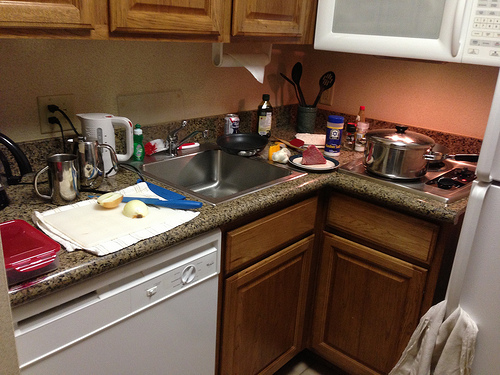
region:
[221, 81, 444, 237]
a kitchen counter top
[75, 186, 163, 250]
a sliced onion on a paper towel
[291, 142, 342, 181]
a piece of red meat on a saucer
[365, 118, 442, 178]
a silver pot on the stove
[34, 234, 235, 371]
dish washer under counter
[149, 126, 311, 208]
stain steel sink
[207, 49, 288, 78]
paper towel holder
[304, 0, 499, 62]
a white marcowave under cabinet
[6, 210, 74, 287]
a bowl with a red top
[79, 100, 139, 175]
a white water pitcher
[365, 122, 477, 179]
a pot on a stove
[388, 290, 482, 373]
a towel hanging on the handle of a refrigerator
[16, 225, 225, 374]
a white dishwasher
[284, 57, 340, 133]
three black utensils in a crock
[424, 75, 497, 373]
a white refrigerator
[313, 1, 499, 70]
a white microwave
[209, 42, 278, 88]
a paper towel roll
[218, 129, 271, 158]
a frying pan next to a sink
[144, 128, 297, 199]
a metal sink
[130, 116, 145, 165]
a bottle of green dish soap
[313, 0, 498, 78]
part of a white microwave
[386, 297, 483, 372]
part of a white rag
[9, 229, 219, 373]
part of a white dishwasher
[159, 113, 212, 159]
a sink faucet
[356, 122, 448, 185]
a large pan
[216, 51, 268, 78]
a roll of paper towels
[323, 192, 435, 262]
a brown cabinet drawer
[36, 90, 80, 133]
a beige wall outlet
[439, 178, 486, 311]
a refrigerator door handle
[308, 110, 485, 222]
part of a granite counter top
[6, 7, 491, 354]
kitchen corner next to refrigerator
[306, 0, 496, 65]
white microwave hanging from above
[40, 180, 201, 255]
blue knife by cut onion on dish cloth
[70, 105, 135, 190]
white pitcher behind silver pitcher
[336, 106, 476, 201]
silver pot on top of stove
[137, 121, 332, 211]
empty sink next to pot and food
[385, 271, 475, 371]
dirty towel hanging from door handle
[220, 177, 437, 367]
brown drawers and cabinet doors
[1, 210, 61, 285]
red lid over food container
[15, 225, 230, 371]
dishwasher under stone counter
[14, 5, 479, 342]
a small cluttered kitchen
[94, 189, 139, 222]
a white onion sliced into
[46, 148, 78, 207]
a metal pitcher on the counter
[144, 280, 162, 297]
a white switch on the dishwasher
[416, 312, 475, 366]
a towel hung on the refridgerator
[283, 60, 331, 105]
black plastic utensils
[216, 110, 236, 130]
a can on soda on the counter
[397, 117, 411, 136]
a black knob on a pot lid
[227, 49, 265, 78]
a white paper towel on a roll